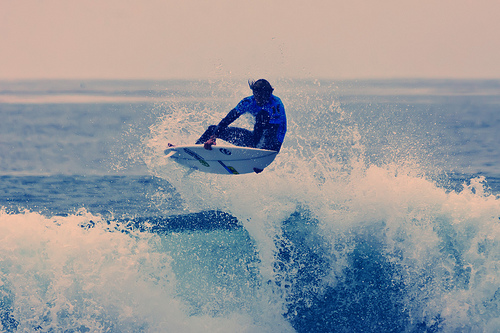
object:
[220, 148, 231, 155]
symbol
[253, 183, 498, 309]
wave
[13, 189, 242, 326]
wave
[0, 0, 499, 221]
air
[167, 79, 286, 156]
man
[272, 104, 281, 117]
logo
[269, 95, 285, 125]
shoulder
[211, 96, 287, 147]
wet suit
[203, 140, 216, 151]
hand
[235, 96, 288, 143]
top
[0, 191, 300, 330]
water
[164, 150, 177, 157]
fin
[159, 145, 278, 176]
board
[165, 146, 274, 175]
base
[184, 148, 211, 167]
fin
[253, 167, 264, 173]
fin